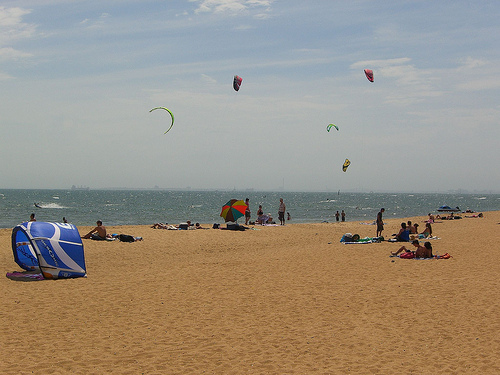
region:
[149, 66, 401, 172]
several kites in the air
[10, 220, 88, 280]
blue and white tent on the ground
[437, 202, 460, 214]
small boat in the ocean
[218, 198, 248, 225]
multicolored umbrella on the beach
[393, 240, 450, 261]
couple on a red towel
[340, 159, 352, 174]
black and yellow kite in the air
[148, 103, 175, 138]
green kite in the air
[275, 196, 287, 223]
man in a white shirt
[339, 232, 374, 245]
green towel on the beach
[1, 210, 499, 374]
sandy beach with people on it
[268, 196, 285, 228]
person on the beach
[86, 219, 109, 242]
person on the beach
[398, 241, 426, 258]
person on the beach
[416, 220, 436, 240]
person on the beach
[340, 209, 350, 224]
person on the beach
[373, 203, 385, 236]
person on the beach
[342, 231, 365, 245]
person on the beach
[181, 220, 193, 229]
person on the beach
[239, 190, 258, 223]
person on the beach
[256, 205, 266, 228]
person on the beach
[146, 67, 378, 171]
kites in the air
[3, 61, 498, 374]
flying kites on a beach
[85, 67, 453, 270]
group of kiteflyers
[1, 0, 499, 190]
mostly cloudy sky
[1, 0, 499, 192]
white clouds and blue sky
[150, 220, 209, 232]
people lying on a sandy beach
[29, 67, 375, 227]
group of kite flyers flying kites on beach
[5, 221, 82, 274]
blue and white kite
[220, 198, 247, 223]
orange blue and turquoise beach umbrella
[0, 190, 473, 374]
sandy ocean beach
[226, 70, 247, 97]
a kite in the air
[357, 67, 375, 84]
a kite in the air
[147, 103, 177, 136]
a kite in the air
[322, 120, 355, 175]
two kites in the air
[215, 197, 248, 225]
a multicolored beach umbrella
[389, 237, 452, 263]
people laying on the sand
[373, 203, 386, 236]
a person standing on the sand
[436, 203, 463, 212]
a boat on the water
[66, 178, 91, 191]
a boat in the distance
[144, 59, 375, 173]
five kites in the air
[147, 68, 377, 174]
several sails in the air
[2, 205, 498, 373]
the sand is golden tan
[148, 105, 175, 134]
the left most sail is green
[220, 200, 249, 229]
the umbrella is multi colored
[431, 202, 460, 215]
boat on the right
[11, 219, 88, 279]
large blue and white arch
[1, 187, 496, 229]
water is blueish grey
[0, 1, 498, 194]
sky is blue and cloudy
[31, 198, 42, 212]
the person is parasailing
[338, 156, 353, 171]
lowest sail is black and yellow